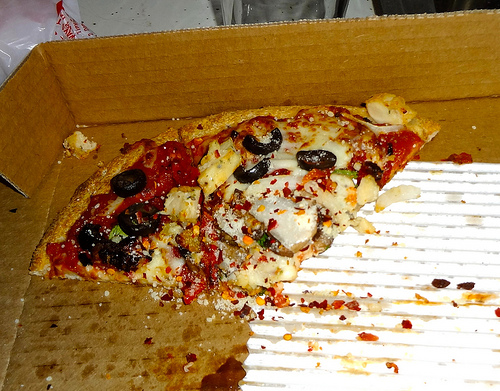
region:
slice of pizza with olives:
[186, 97, 430, 305]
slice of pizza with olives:
[41, 128, 266, 326]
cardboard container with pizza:
[35, 32, 499, 376]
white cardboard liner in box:
[236, 168, 499, 388]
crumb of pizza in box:
[54, 124, 103, 172]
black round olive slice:
[110, 165, 148, 197]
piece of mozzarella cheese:
[246, 160, 328, 252]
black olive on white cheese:
[293, 148, 340, 172]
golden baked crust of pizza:
[178, 93, 442, 142]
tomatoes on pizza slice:
[177, 251, 226, 311]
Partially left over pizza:
[29, 91, 440, 315]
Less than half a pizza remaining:
[29, 105, 444, 308]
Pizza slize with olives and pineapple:
[173, 97, 444, 295]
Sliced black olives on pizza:
[230, 119, 341, 184]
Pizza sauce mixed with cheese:
[29, 125, 215, 304]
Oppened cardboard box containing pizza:
[0, 8, 498, 389]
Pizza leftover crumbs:
[152, 276, 489, 361]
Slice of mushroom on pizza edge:
[359, 91, 423, 128]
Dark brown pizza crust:
[22, 118, 173, 290]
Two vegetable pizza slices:
[26, 95, 439, 320]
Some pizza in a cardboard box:
[17, 20, 491, 372]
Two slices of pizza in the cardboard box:
[56, 101, 416, 312]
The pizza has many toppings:
[220, 111, 382, 300]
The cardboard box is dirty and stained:
[36, 294, 229, 386]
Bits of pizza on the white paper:
[273, 269, 466, 346]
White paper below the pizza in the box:
[307, 200, 489, 389]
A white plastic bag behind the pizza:
[8, 0, 113, 61]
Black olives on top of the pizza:
[117, 160, 157, 249]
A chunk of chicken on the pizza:
[200, 133, 240, 198]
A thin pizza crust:
[182, 90, 430, 138]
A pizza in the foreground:
[13, 78, 453, 333]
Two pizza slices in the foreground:
[23, 83, 442, 320]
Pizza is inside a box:
[8, 11, 499, 388]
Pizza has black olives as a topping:
[56, 120, 358, 310]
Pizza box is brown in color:
[0, 13, 498, 388]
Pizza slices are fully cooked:
[16, 78, 463, 340]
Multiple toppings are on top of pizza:
[187, 132, 377, 307]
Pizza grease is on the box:
[28, 281, 246, 387]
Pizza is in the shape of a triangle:
[16, 93, 463, 343]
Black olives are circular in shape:
[97, 163, 171, 248]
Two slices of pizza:
[21, 97, 442, 301]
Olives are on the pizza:
[78, 125, 381, 270]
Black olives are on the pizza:
[65, 126, 387, 271]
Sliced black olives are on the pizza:
[77, 123, 382, 270]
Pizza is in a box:
[3, 10, 496, 389]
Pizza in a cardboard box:
[5, 10, 496, 387]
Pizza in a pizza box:
[1, 7, 497, 389]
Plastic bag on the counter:
[2, 2, 104, 89]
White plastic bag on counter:
[0, 0, 101, 92]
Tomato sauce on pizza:
[55, 107, 415, 276]